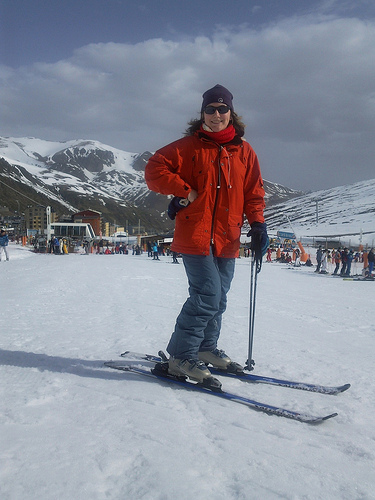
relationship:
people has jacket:
[137, 70, 285, 409] [144, 135, 266, 257]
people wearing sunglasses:
[137, 70, 285, 409] [204, 103, 230, 115]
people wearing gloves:
[137, 70, 285, 409] [168, 194, 267, 256]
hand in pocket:
[187, 191, 199, 203] [179, 193, 203, 240]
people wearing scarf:
[137, 70, 285, 409] [194, 125, 238, 143]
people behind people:
[2, 229, 182, 265] [137, 70, 285, 409]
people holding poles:
[137, 70, 285, 409] [245, 251, 257, 370]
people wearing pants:
[137, 70, 285, 409] [166, 245, 233, 361]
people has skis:
[137, 70, 285, 409] [101, 349, 349, 426]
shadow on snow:
[1, 350, 156, 382] [0, 253, 372, 500]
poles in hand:
[245, 251, 257, 370] [247, 222, 270, 258]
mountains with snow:
[0, 135, 374, 258] [0, 135, 372, 243]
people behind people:
[238, 241, 372, 281] [137, 70, 285, 409]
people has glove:
[137, 70, 285, 409] [168, 195, 188, 218]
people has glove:
[137, 70, 285, 409] [247, 222, 268, 257]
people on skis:
[137, 70, 285, 409] [101, 349, 349, 426]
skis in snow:
[101, 349, 349, 426] [0, 253, 372, 500]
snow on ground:
[0, 253, 372, 500] [2, 253, 374, 500]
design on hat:
[219, 98, 222, 106] [201, 85, 231, 108]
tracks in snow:
[2, 269, 374, 499] [0, 253, 372, 500]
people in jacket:
[137, 70, 285, 409] [144, 135, 266, 257]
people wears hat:
[137, 70, 285, 409] [201, 85, 231, 108]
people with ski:
[137, 70, 285, 409] [107, 350, 350, 397]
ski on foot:
[107, 350, 350, 397] [197, 348, 233, 369]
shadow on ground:
[1, 350, 156, 382] [2, 253, 374, 500]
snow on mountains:
[0, 135, 372, 243] [0, 135, 374, 258]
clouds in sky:
[1, 1, 374, 192] [1, 4, 373, 193]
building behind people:
[73, 208, 104, 244] [137, 70, 285, 409]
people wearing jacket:
[137, 70, 285, 409] [144, 135, 266, 257]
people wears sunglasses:
[137, 70, 285, 409] [204, 103, 230, 115]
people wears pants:
[137, 70, 285, 409] [166, 245, 233, 361]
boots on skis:
[167, 347, 231, 381] [101, 349, 349, 426]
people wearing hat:
[137, 70, 285, 409] [201, 85, 231, 108]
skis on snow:
[101, 349, 349, 426] [0, 253, 372, 500]